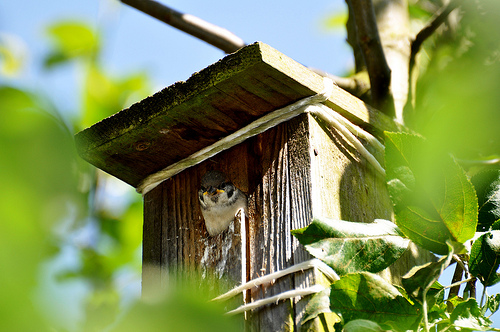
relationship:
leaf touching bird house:
[469, 230, 499, 284] [72, 41, 439, 330]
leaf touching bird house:
[326, 274, 414, 330] [72, 41, 439, 330]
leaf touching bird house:
[381, 130, 478, 254] [72, 41, 439, 330]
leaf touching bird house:
[290, 217, 413, 269] [72, 41, 439, 330]